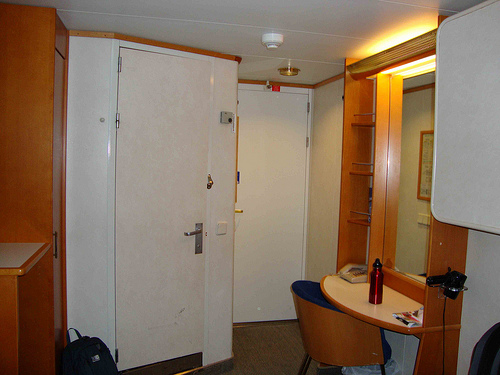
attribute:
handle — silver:
[164, 212, 222, 261]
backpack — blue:
[53, 327, 124, 372]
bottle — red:
[368, 256, 386, 306]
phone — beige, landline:
[335, 261, 371, 284]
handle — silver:
[184, 223, 205, 239]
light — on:
[380, 22, 414, 51]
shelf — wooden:
[337, 72, 399, 269]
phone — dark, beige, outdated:
[338, 260, 368, 285]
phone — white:
[336, 250, 386, 293]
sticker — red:
[262, 85, 287, 97]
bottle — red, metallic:
[363, 253, 386, 309]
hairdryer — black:
[427, 265, 469, 299]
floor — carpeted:
[237, 324, 294, 374]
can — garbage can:
[325, 360, 388, 374]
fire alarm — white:
[259, 36, 294, 53]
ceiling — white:
[317, 19, 371, 40]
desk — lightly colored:
[248, 198, 465, 368]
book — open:
[394, 306, 421, 333]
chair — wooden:
[285, 280, 382, 373]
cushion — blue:
[294, 278, 329, 304]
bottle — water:
[353, 257, 393, 305]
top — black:
[369, 259, 385, 267]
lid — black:
[370, 258, 383, 268]